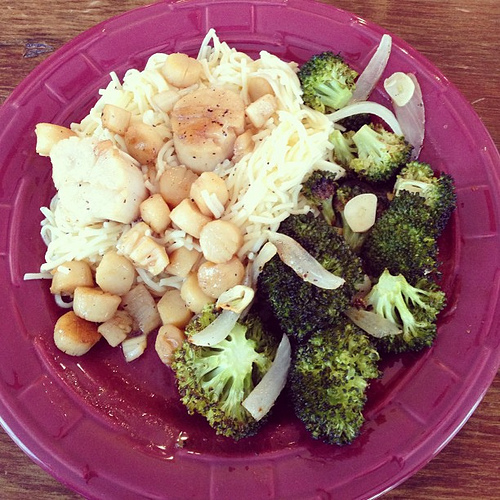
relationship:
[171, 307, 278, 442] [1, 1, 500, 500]
broccoli sitting on plate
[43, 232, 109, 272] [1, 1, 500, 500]
noodle on top of plate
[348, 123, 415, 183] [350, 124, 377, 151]
broccoli has stem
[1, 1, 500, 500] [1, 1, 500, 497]
plate sitting on table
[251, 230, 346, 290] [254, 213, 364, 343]
onion on top of broccoli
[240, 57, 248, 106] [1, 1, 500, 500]
noodle sitting on plate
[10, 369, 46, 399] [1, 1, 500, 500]
groove in side of plate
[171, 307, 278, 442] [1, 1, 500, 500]
broccoli laying on plate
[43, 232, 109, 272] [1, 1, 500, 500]
noodle served on plate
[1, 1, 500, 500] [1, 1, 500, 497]
plate resting on table